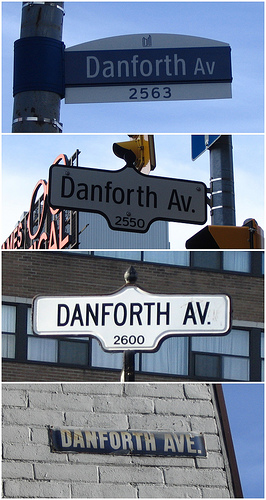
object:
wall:
[1, 384, 233, 498]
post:
[14, 1, 64, 135]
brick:
[0, 407, 63, 429]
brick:
[63, 410, 132, 435]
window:
[191, 327, 251, 360]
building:
[1, 252, 263, 379]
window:
[3, 301, 25, 365]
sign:
[65, 34, 234, 105]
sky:
[222, 382, 260, 499]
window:
[256, 330, 264, 379]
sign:
[45, 426, 207, 464]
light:
[114, 142, 136, 165]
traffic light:
[111, 132, 158, 175]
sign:
[49, 161, 208, 236]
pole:
[210, 134, 238, 226]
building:
[3, 384, 235, 497]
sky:
[0, 132, 263, 253]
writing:
[163, 432, 197, 456]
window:
[26, 308, 59, 364]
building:
[6, 191, 166, 249]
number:
[114, 212, 147, 229]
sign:
[30, 283, 229, 355]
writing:
[58, 301, 209, 329]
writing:
[59, 172, 196, 219]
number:
[113, 333, 147, 345]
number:
[128, 83, 173, 102]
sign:
[3, 150, 91, 252]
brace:
[204, 174, 234, 187]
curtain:
[93, 342, 126, 370]